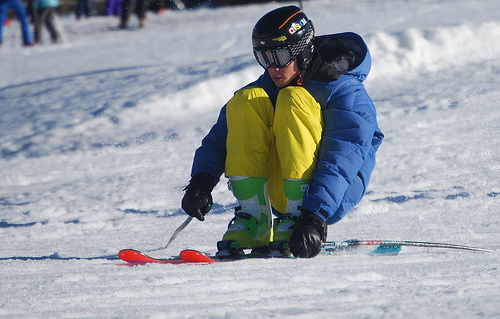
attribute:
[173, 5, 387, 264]
person crouched — on skis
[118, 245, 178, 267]
ski — orange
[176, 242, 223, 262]
ski — orange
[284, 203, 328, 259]
glove — black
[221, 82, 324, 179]
pants — yellow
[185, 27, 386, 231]
jacket — blue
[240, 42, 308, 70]
googles — black, white, for ski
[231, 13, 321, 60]
helmet — black, stripe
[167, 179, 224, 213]
glove — black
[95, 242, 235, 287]
ski — reddish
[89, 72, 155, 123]
snow — white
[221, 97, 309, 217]
pants — for snow, bag, yellow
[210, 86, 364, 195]
jacket — blue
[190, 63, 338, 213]
jacket — blue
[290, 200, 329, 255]
gloves — black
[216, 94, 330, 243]
pants — yellow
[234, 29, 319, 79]
glasses — for skiing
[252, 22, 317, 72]
helment — black, for skiing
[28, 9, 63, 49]
pants — black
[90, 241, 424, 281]
skis — orange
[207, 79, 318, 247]
pants — yellow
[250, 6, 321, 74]
helment — black